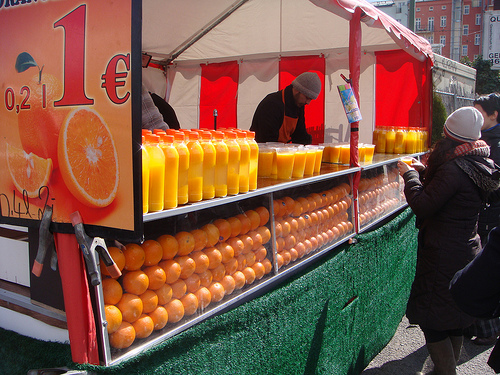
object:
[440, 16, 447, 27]
window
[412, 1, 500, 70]
building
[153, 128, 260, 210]
orange juice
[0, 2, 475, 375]
booth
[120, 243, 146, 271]
orange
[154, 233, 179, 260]
orange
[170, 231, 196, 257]
orange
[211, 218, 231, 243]
orange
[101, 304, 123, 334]
orange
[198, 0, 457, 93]
tent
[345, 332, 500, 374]
shadow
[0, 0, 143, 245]
advertisement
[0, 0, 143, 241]
advertisement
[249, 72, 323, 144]
man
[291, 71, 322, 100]
beanie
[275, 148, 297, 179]
glasses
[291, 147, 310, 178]
glasses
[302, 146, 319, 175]
glasses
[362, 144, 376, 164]
glasses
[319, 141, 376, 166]
glasses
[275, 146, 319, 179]
orange juice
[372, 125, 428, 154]
orange juice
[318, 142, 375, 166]
orange juice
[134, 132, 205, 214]
orange juice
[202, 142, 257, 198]
orange juice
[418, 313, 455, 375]
boot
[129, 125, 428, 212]
orange juice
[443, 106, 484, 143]
stocking cap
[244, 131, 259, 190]
orange juice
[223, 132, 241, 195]
orange juice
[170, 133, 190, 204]
orange juice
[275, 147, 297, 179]
orange juice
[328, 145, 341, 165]
orange juice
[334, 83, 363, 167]
stand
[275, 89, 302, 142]
apron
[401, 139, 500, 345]
coat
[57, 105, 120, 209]
orange half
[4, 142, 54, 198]
orange slice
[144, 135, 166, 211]
bottle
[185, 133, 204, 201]
bottle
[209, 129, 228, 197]
bottle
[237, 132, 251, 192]
bottle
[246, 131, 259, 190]
bottle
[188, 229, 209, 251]
orange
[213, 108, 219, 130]
handle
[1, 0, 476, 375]
shop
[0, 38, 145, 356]
door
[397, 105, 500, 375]
person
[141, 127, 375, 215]
counter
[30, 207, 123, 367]
clamps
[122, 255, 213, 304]
orange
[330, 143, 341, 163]
orange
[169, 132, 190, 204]
juice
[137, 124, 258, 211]
orange juice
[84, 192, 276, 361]
display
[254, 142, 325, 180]
glasses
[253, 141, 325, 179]
juice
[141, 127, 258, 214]
bottle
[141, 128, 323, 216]
display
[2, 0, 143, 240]
banner